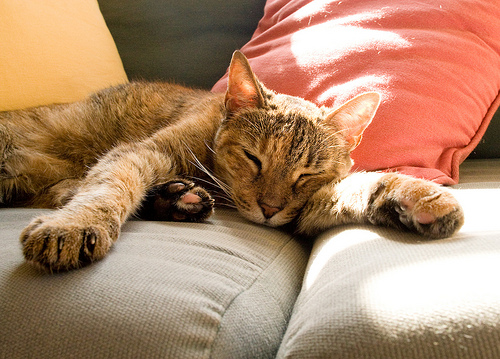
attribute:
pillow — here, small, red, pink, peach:
[208, 5, 497, 184]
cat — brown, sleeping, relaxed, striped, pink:
[2, 49, 464, 272]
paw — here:
[377, 173, 467, 237]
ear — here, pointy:
[226, 48, 268, 108]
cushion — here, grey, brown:
[1, 202, 310, 358]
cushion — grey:
[273, 158, 500, 354]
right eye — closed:
[294, 167, 324, 194]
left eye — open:
[244, 146, 263, 182]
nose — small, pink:
[260, 198, 282, 218]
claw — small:
[88, 234, 98, 246]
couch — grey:
[0, 2, 499, 357]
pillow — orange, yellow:
[2, 4, 128, 115]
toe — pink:
[179, 192, 202, 203]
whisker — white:
[179, 139, 230, 195]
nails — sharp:
[43, 234, 102, 249]